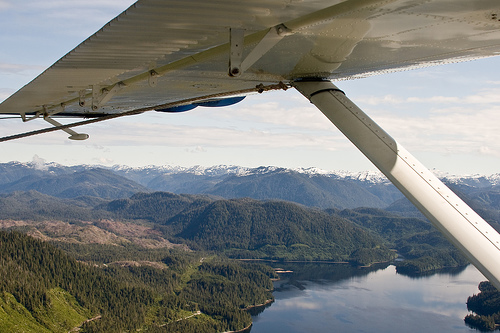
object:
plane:
[0, 0, 500, 288]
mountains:
[0, 155, 499, 333]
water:
[244, 261, 482, 333]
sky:
[0, 0, 500, 176]